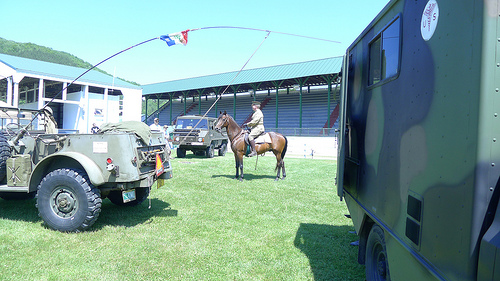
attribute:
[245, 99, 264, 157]
man — soldier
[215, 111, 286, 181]
horse — brown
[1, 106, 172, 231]
jeep — military, camo, vehicle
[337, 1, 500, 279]
troop carrier — camouflage, large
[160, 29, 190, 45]
flag — red,white,, blue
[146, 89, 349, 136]
grandstand — empty, for spectators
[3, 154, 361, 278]
grass — short, green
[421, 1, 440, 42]
symbol — medical, u.s.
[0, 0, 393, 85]
sky — blue, clear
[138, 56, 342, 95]
roof — blue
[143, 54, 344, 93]
roof — green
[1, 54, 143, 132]
building — white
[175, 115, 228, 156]
vehicle — military